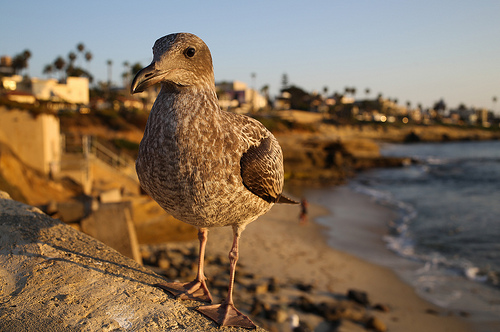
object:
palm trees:
[43, 40, 93, 80]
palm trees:
[341, 83, 369, 101]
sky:
[5, 4, 113, 45]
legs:
[192, 220, 261, 330]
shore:
[313, 173, 455, 311]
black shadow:
[0, 211, 163, 287]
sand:
[269, 214, 313, 254]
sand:
[305, 252, 384, 285]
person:
[299, 197, 308, 221]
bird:
[128, 31, 302, 328]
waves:
[353, 172, 463, 219]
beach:
[293, 171, 463, 303]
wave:
[391, 225, 470, 292]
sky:
[245, 5, 498, 85]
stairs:
[81, 133, 132, 178]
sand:
[393, 307, 423, 328]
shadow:
[1, 208, 174, 298]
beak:
[126, 63, 168, 94]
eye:
[183, 46, 200, 58]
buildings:
[270, 85, 321, 115]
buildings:
[449, 105, 488, 125]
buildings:
[353, 100, 415, 120]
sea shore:
[334, 117, 496, 312]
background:
[223, 22, 495, 120]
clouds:
[289, 15, 416, 75]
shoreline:
[335, 182, 424, 262]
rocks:
[259, 276, 309, 316]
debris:
[324, 288, 387, 323]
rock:
[2, 201, 153, 330]